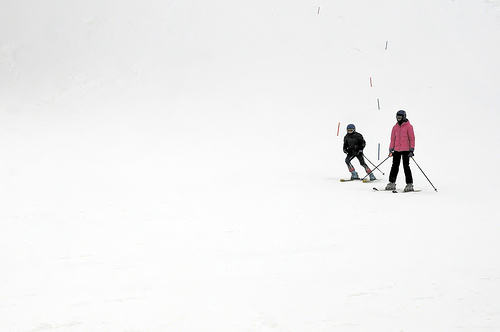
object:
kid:
[384, 110, 415, 191]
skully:
[396, 110, 405, 120]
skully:
[347, 125, 355, 132]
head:
[395, 110, 407, 122]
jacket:
[388, 119, 416, 152]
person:
[342, 123, 375, 180]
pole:
[337, 121, 341, 137]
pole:
[369, 77, 373, 87]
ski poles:
[410, 152, 437, 192]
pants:
[388, 151, 415, 184]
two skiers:
[338, 110, 438, 193]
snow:
[1, 0, 500, 332]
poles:
[317, 6, 321, 14]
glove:
[389, 151, 393, 156]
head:
[346, 123, 356, 135]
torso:
[348, 147, 362, 155]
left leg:
[358, 155, 377, 181]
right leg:
[345, 154, 357, 175]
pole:
[362, 154, 385, 175]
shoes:
[350, 171, 359, 180]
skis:
[339, 178, 361, 183]